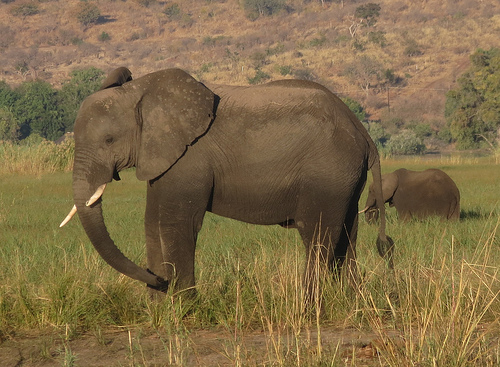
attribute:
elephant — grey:
[59, 64, 393, 298]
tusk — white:
[85, 183, 107, 206]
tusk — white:
[53, 207, 76, 226]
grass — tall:
[1, 135, 498, 364]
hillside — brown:
[0, 2, 498, 147]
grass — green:
[219, 250, 412, 327]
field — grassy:
[36, 177, 173, 262]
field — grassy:
[376, 213, 480, 275]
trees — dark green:
[6, 66, 109, 133]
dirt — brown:
[156, 297, 351, 341]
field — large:
[33, 216, 487, 354]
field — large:
[23, 114, 493, 352]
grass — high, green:
[292, 232, 469, 362]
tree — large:
[425, 38, 498, 171]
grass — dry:
[324, 253, 477, 363]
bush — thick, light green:
[7, 126, 71, 180]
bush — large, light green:
[365, 118, 430, 161]